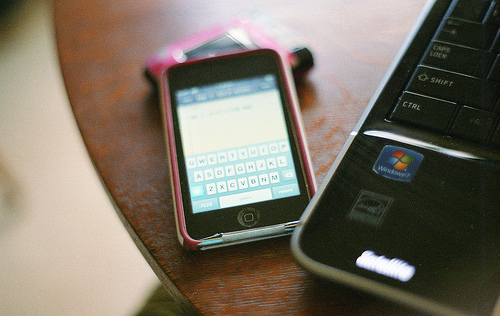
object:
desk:
[49, 0, 498, 316]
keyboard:
[183, 138, 301, 215]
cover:
[157, 49, 317, 250]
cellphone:
[157, 47, 317, 253]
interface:
[166, 58, 275, 82]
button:
[236, 207, 260, 227]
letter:
[262, 177, 267, 182]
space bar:
[218, 188, 272, 208]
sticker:
[373, 145, 425, 183]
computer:
[290, 0, 500, 316]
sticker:
[346, 190, 393, 226]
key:
[404, 64, 499, 114]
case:
[144, 19, 313, 90]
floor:
[2, 195, 97, 316]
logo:
[354, 249, 416, 282]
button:
[388, 91, 456, 135]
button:
[420, 40, 494, 79]